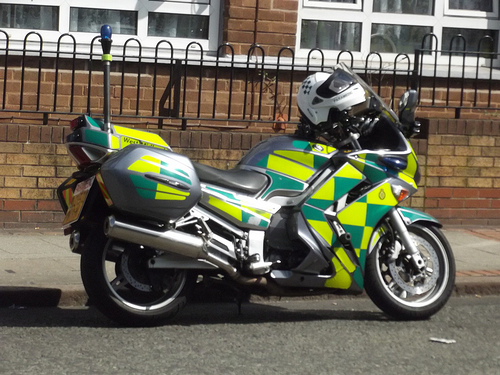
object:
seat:
[190, 158, 267, 194]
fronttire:
[363, 206, 457, 320]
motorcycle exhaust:
[103, 214, 228, 267]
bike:
[57, 62, 456, 328]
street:
[2, 299, 494, 373]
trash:
[428, 336, 458, 345]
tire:
[79, 215, 196, 326]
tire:
[364, 217, 456, 318]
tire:
[79, 236, 123, 314]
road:
[2, 293, 500, 375]